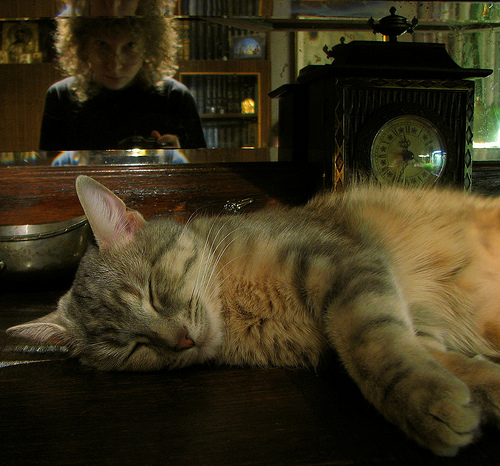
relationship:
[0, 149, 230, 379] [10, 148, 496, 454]
head of cat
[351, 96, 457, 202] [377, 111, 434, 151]
clock has roman numerals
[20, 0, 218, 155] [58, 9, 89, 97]
lady has curly hair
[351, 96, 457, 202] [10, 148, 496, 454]
clock behind cat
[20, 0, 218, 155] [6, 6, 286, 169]
lady i mirror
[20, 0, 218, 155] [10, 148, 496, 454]
lady with cat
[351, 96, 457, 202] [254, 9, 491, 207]
clock i brow box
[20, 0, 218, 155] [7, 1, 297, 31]
lady has reflectio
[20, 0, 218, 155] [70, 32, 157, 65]
lady wears glasses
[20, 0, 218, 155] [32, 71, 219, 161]
lady wears black shirt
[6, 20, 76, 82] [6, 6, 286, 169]
poster i mirror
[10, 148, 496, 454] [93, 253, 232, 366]
cat has face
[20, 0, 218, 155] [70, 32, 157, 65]
lady has glasses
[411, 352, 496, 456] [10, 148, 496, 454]
paws are o cat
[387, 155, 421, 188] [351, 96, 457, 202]
arms of clock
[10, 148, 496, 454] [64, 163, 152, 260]
cat has ear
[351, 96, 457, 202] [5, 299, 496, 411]
clock of shelf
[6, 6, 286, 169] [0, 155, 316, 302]
mirror of dresser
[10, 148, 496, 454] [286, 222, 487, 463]
cat has frot leg